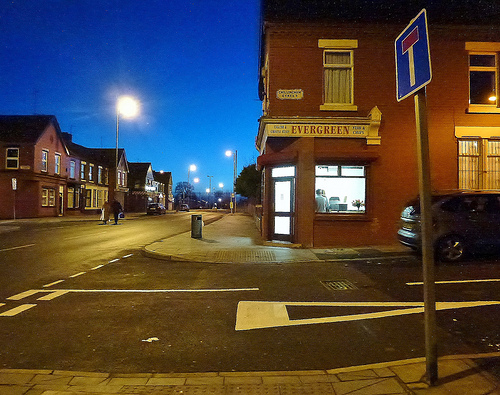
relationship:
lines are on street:
[231, 290, 498, 328] [8, 259, 495, 364]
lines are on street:
[434, 271, 499, 288] [8, 259, 495, 364]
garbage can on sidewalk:
[191, 215, 204, 239] [144, 216, 261, 265]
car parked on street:
[403, 194, 498, 278] [8, 259, 495, 364]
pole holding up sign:
[409, 93, 451, 386] [392, 7, 432, 103]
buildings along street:
[1, 123, 201, 229] [9, 174, 222, 361]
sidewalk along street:
[1, 351, 499, 393] [8, 259, 495, 364]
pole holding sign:
[410, 93, 443, 385] [385, 4, 437, 107]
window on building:
[309, 159, 369, 216] [245, 2, 497, 251]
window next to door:
[309, 159, 369, 216] [262, 160, 304, 242]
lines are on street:
[0, 237, 40, 253] [4, 221, 135, 284]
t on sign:
[398, 24, 423, 87] [387, 6, 442, 106]